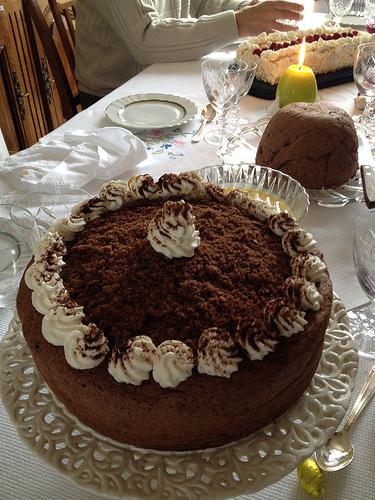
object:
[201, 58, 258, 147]
glass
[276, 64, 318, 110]
yellow color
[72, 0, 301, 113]
person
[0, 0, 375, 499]
table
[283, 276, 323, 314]
vanilla frosting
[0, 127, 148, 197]
napkin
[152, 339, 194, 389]
whip cream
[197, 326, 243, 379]
whip cream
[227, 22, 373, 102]
cake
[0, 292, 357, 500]
plate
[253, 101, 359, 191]
cake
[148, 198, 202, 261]
icing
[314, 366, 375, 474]
spoon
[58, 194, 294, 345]
crumbles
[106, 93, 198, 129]
plate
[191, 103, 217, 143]
spoon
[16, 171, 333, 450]
cakes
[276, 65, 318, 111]
candle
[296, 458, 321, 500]
chocolate egg